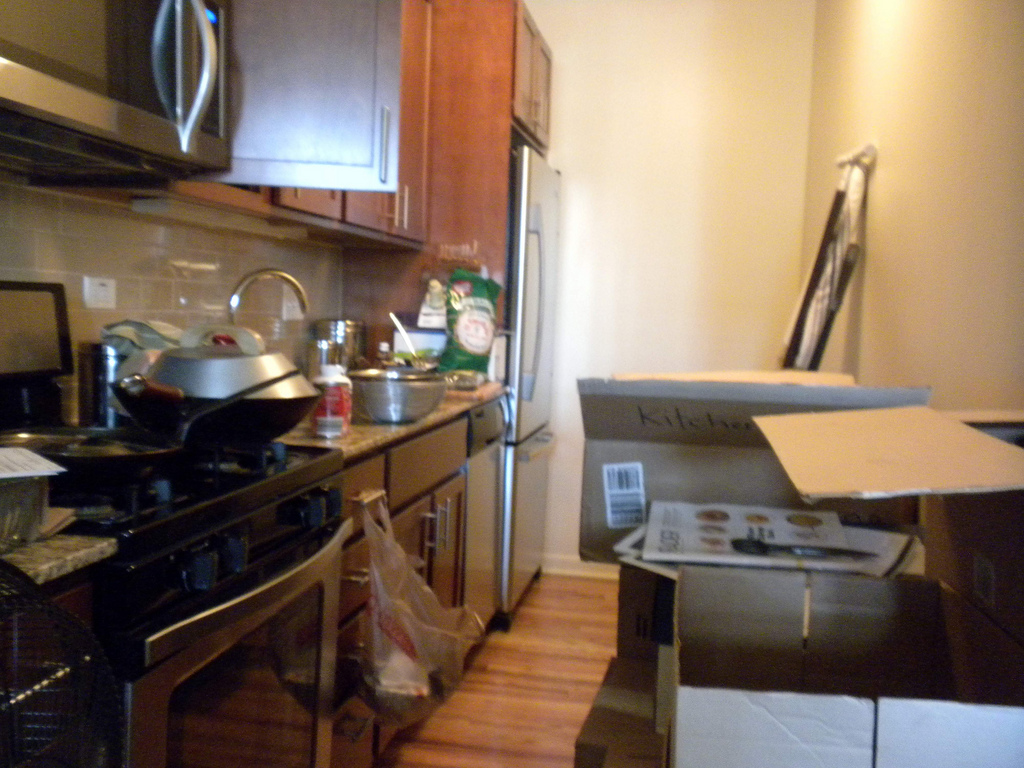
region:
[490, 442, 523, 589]
edge of white fridge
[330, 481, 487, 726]
clear plastic bag on hook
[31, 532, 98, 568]
gray stone top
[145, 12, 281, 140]
silver handle of microwave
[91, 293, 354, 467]
black wok with silver lid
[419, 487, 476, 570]
silver handles on kitchen cabinet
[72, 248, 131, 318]
white electrical outlet on wall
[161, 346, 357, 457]
black skillet handle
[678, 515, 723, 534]
food on the paper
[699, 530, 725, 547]
food on the paper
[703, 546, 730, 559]
food on the paper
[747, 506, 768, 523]
food on the paper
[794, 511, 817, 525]
food on the paper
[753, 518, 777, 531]
food on the paper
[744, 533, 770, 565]
food on the paper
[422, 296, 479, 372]
object on the counter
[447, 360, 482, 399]
object on the counter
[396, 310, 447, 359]
object on the counter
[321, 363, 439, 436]
object on the counter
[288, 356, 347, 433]
object on the counter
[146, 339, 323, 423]
object on the counter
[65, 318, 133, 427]
object on the counter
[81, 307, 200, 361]
object on the counter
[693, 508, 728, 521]
food on the paper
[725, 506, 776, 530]
food on the paper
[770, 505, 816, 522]
food on the paper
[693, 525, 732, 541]
food on the paper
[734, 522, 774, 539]
food on the paper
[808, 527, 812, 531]
food on the paper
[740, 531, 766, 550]
food on the paper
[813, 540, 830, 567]
food on the paper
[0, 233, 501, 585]
a messy kitchen counter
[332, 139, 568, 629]
a stainless steel refrigerator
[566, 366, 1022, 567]
a cardboard box being unpacked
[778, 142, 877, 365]
an object propped up against the wall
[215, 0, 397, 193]
an open cabinet door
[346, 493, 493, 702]
a bag hanging on the drawer handle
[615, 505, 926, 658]
a box on top of a box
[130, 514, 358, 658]
the handle of the oven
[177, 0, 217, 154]
the handle of the microwave oven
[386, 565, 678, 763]
hardwood floor in the kitchen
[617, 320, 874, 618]
a box on the counter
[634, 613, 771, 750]
a box on the counter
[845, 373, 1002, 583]
a box on the counter